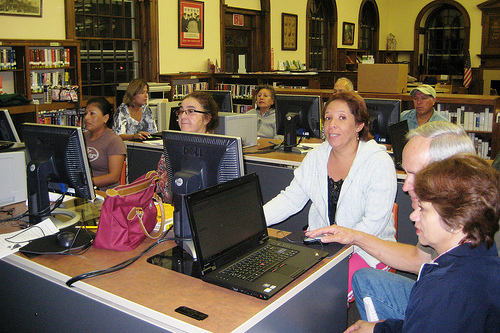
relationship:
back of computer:
[19, 123, 93, 202] [363, 94, 401, 142]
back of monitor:
[19, 123, 93, 202] [18, 120, 96, 203]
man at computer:
[401, 83, 440, 129] [363, 94, 401, 142]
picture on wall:
[176, 1, 208, 52] [1, 4, 398, 89]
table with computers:
[127, 129, 430, 246] [204, 84, 402, 147]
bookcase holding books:
[1, 42, 86, 132] [24, 44, 76, 125]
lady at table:
[251, 84, 280, 143] [127, 129, 430, 246]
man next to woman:
[400, 115, 475, 211] [345, 157, 500, 332]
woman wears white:
[257, 91, 396, 246] [354, 155, 397, 236]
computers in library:
[204, 84, 402, 147] [5, 0, 491, 224]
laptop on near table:
[179, 173, 326, 298] [1, 190, 356, 332]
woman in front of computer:
[257, 91, 396, 246] [158, 127, 245, 267]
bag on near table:
[96, 162, 166, 251] [1, 190, 356, 332]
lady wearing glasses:
[105, 86, 214, 195] [173, 104, 211, 122]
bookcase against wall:
[1, 42, 86, 132] [1, 4, 398, 89]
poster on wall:
[283, 11, 297, 52] [1, 4, 398, 89]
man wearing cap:
[401, 83, 440, 129] [410, 78, 436, 99]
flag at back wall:
[459, 42, 474, 96] [391, 0, 499, 94]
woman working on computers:
[257, 91, 396, 246] [1, 106, 245, 245]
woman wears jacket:
[257, 91, 396, 246] [264, 140, 399, 241]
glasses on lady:
[173, 104, 211, 122] [105, 86, 214, 195]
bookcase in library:
[1, 42, 86, 132] [5, 0, 491, 224]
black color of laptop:
[213, 212, 261, 255] [179, 173, 326, 298]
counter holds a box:
[258, 86, 495, 100] [360, 58, 414, 98]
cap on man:
[410, 78, 436, 99] [401, 83, 440, 129]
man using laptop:
[400, 115, 475, 211] [179, 173, 326, 298]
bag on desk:
[96, 162, 166, 251] [1, 190, 356, 332]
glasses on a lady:
[173, 104, 211, 122] [105, 86, 214, 195]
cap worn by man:
[410, 78, 436, 99] [401, 83, 440, 129]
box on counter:
[360, 58, 414, 98] [258, 86, 495, 100]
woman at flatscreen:
[345, 157, 500, 332] [183, 173, 271, 265]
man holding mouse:
[400, 115, 475, 211] [293, 227, 334, 254]